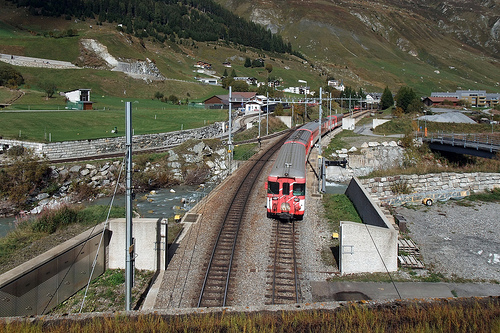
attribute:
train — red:
[252, 107, 342, 224]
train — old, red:
[264, 122, 312, 218]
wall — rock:
[360, 177, 497, 197]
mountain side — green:
[2, 0, 499, 102]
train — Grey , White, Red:
[265, 110, 346, 222]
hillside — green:
[0, 2, 500, 141]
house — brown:
[196, 85, 275, 115]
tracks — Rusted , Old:
[195, 220, 323, 301]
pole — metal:
[121, 96, 149, 313]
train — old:
[256, 125, 315, 224]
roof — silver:
[265, 139, 307, 184]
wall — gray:
[340, 173, 403, 269]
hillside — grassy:
[0, 36, 500, 113]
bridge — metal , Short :
[397, 130, 497, 162]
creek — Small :
[1, 179, 212, 225]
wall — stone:
[374, 169, 480, 205]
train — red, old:
[236, 150, 350, 238]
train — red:
[253, 93, 358, 227]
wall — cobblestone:
[63, 132, 190, 156]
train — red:
[268, 120, 320, 220]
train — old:
[262, 171, 307, 226]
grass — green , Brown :
[0, 292, 499, 331]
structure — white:
[62, 85, 101, 127]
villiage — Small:
[188, 58, 476, 110]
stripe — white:
[296, 197, 304, 215]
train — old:
[266, 174, 306, 222]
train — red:
[268, 118, 308, 219]